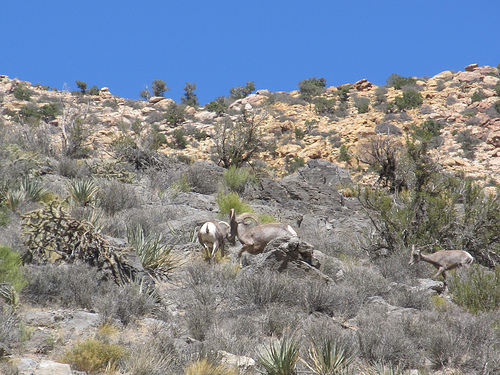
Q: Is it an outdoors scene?
A: Yes, it is outdoors.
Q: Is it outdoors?
A: Yes, it is outdoors.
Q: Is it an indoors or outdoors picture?
A: It is outdoors.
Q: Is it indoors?
A: No, it is outdoors.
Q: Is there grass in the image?
A: Yes, there is grass.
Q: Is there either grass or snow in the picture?
A: Yes, there is grass.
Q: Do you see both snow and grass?
A: No, there is grass but no snow.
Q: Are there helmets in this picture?
A: No, there are no helmets.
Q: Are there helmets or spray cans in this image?
A: No, there are no helmets or spray cans.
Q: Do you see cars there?
A: No, there are no cars.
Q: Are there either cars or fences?
A: No, there are no cars or fences.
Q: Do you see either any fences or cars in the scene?
A: No, there are no cars or fences.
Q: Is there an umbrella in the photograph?
A: No, there are no umbrellas.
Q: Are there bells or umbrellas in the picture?
A: No, there are no umbrellas or bells.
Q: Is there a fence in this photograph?
A: No, there are no fences.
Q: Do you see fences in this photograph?
A: No, there are no fences.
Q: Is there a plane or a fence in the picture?
A: No, there are no fences or airplanes.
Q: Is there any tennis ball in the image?
A: No, there are no tennis balls.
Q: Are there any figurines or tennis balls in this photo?
A: No, there are no tennis balls or figurines.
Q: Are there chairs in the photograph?
A: No, there are no chairs.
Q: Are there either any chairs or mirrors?
A: No, there are no chairs or mirrors.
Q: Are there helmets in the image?
A: No, there are no helmets.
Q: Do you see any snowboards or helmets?
A: No, there are no helmets or snowboards.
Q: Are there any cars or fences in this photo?
A: No, there are no cars or fences.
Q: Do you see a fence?
A: No, there are no fences.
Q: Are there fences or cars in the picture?
A: No, there are no fences or cars.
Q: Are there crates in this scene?
A: No, there are no crates.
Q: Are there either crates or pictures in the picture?
A: No, there are no crates or pictures.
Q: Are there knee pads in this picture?
A: No, there are no knee pads.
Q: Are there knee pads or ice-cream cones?
A: No, there are no knee pads or ice-cream cones.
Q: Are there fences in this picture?
A: No, there are no fences.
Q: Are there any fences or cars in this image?
A: No, there are no fences or cars.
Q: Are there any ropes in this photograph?
A: No, there are no ropes.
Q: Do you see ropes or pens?
A: No, there are no ropes or pens.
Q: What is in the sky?
A: The clouds are in the sky.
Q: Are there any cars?
A: No, there are no cars.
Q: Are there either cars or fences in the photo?
A: No, there are no cars or fences.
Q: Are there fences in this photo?
A: No, there are no fences.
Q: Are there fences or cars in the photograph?
A: No, there are no fences or cars.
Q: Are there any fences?
A: No, there are no fences.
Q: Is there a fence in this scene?
A: No, there are no fences.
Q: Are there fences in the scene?
A: No, there are no fences.